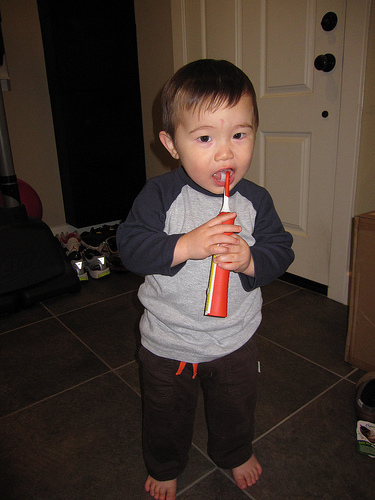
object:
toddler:
[117, 57, 297, 498]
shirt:
[116, 173, 294, 364]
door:
[172, 0, 371, 303]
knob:
[312, 51, 331, 73]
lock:
[320, 11, 338, 32]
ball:
[14, 176, 43, 221]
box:
[342, 209, 373, 377]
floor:
[0, 280, 374, 499]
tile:
[110, 322, 341, 470]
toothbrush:
[205, 170, 237, 318]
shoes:
[55, 222, 89, 282]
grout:
[253, 377, 343, 453]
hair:
[160, 58, 261, 131]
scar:
[219, 115, 227, 132]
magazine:
[355, 419, 375, 457]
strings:
[175, 359, 198, 379]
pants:
[140, 341, 258, 480]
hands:
[192, 212, 235, 272]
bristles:
[219, 173, 227, 181]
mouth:
[212, 166, 235, 187]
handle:
[205, 211, 237, 317]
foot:
[232, 453, 261, 490]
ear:
[158, 130, 179, 159]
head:
[162, 58, 260, 198]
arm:
[253, 192, 293, 290]